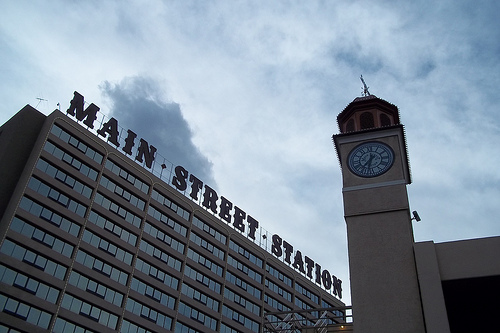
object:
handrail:
[259, 301, 356, 331]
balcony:
[263, 307, 366, 332]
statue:
[356, 75, 371, 98]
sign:
[63, 89, 343, 303]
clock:
[345, 141, 396, 179]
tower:
[330, 71, 427, 332]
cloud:
[94, 68, 222, 199]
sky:
[0, 0, 500, 323]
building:
[0, 101, 345, 332]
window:
[50, 122, 63, 137]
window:
[44, 138, 55, 155]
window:
[34, 157, 50, 173]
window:
[26, 173, 41, 191]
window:
[19, 194, 33, 212]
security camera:
[411, 210, 423, 222]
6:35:
[359, 152, 379, 173]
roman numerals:
[365, 144, 374, 153]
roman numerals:
[374, 143, 381, 153]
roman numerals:
[379, 148, 386, 156]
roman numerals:
[380, 154, 391, 160]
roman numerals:
[379, 160, 389, 167]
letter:
[65, 89, 100, 129]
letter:
[96, 116, 121, 148]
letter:
[121, 128, 138, 157]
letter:
[133, 137, 159, 170]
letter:
[170, 165, 189, 191]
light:
[338, 323, 345, 332]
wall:
[323, 320, 353, 332]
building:
[330, 95, 498, 330]